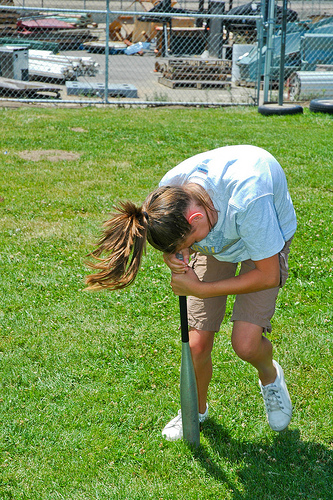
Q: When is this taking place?
A: Daytime.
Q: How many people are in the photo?
A: One.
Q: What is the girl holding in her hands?
A: Bat.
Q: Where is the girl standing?
A: Grass.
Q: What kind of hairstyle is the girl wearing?
A: Ponytail.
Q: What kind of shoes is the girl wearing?
A: Sneakers.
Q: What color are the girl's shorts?
A: Tan.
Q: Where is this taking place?
A: At a park.